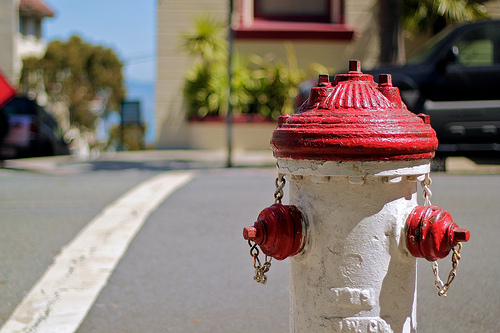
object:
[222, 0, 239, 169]
post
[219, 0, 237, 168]
tall